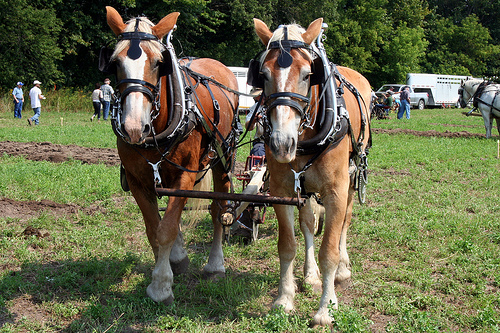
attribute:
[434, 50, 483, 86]
bush — green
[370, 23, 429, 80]
bush — green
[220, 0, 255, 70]
bush — green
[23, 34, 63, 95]
bush — green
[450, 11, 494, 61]
bush — green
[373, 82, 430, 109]
truck — silver 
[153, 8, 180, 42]
ear — small , pointy , brown 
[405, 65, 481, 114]
horse trailer — white 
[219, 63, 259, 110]
horse trailer — white 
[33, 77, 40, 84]
hat — white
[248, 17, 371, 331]
horse — large , brown , white 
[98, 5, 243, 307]
horse — large , brown , hairy 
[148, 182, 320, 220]
pole — long, wide, round